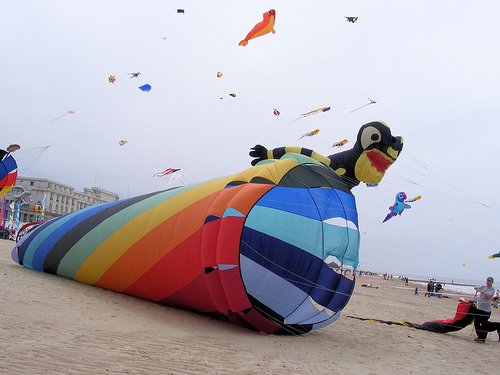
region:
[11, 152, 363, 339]
A large multi colored kite on the ground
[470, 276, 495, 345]
A person in a grey shirt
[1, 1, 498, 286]
A grey cloudy sky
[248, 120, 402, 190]
A black and yellow kite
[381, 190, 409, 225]
A blue and pink kite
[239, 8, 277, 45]
an orange and yellow kite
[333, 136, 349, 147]
A kite in the sky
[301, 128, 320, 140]
A kite in the sky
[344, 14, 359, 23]
A kite in the sky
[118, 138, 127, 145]
A kite in the sky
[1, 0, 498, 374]
the kites at the beach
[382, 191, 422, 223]
the kite in the sky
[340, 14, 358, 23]
the kite in the sky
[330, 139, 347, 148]
the kite in the sky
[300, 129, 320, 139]
the kite in the sky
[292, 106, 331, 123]
the kite in the sky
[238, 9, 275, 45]
the kite in the sky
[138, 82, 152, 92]
the kite in the sky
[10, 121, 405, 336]
the large kite on the ground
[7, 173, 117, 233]
the building in the distance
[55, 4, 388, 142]
many kites flying in the air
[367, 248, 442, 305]
people on the beach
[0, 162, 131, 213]
building in the background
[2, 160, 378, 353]
the tunnel is multi colored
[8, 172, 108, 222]
the building is white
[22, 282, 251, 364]
the sand is beige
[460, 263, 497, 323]
man looking at the camera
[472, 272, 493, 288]
man is wearing a hat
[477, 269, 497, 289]
the hat is grey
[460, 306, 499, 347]
man is wearing black pants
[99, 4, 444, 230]
many kites flying in the air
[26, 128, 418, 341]
large kite getting ready for take off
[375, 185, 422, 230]
a kite in the shape of a bird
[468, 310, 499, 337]
a dog next to a human on the beach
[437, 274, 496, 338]
kite flyer preparing his kite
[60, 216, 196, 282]
multicolored fabric of a kite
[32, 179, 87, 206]
a building in the background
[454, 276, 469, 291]
the ocean in the background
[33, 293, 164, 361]
sand of the beach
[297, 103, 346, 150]
kites flying through the air with long tails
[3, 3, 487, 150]
kites in the sky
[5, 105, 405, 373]
multicolor kite on the sand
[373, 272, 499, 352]
man holding a kite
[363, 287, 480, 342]
a kite on the sand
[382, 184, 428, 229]
kite shaped like a bird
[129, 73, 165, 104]
a blue kite in the cloudy sky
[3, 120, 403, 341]
a building behind the kite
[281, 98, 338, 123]
kite has long tail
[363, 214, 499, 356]
people in front the sea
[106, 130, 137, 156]
a yellow kite